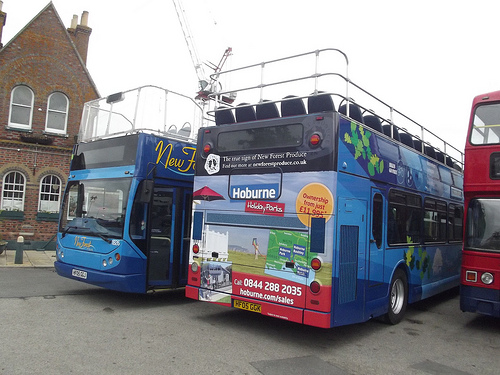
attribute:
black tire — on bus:
[388, 260, 410, 322]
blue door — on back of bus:
[366, 183, 393, 301]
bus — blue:
[186, 44, 461, 332]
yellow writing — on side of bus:
[153, 138, 194, 174]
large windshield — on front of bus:
[59, 175, 129, 243]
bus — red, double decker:
[455, 86, 499, 314]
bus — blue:
[53, 84, 202, 295]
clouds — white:
[94, 5, 199, 38]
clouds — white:
[195, 9, 286, 43]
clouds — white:
[285, 7, 386, 41]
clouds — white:
[379, 1, 499, 51]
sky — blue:
[1, 1, 498, 98]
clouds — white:
[68, 2, 181, 42]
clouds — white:
[141, 0, 259, 47]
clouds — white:
[216, 2, 333, 45]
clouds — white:
[314, 0, 468, 54]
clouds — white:
[94, 4, 194, 53]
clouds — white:
[158, 2, 268, 42]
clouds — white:
[260, 7, 381, 56]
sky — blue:
[1, 1, 497, 116]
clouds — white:
[91, 1, 201, 51]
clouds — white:
[188, 2, 299, 52]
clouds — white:
[287, 1, 387, 52]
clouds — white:
[360, 3, 498, 61]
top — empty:
[193, 47, 464, 194]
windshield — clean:
[57, 170, 137, 238]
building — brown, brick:
[0, 0, 100, 249]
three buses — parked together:
[51, 47, 484, 334]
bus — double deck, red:
[50, 83, 192, 298]